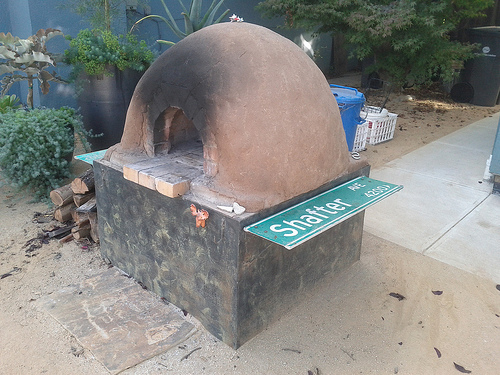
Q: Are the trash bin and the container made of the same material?
A: Yes, both the trash bin and the container are made of plastic.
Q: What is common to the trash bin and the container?
A: The material, both the trash bin and the container are plastic.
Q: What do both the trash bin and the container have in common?
A: The material, both the trash bin and the container are plastic.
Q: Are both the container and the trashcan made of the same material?
A: Yes, both the container and the trashcan are made of plastic.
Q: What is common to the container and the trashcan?
A: The material, both the container and the trashcan are plastic.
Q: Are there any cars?
A: No, there are no cars.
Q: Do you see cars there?
A: No, there are no cars.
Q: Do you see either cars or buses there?
A: No, there are no cars or buses.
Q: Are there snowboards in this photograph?
A: No, there are no snowboards.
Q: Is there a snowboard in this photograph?
A: No, there are no snowboards.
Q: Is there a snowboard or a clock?
A: No, there are no snowboards or clocks.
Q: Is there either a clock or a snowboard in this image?
A: No, there are no snowboards or clocks.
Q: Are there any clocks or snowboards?
A: No, there are no snowboards or clocks.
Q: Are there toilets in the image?
A: No, there are no toilets.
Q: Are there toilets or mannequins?
A: No, there are no toilets or mannequins.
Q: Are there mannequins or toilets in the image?
A: No, there are no toilets or mannequins.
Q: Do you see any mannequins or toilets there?
A: No, there are no toilets or mannequins.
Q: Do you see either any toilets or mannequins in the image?
A: No, there are no toilets or mannequins.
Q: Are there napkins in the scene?
A: No, there are no napkins.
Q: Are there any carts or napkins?
A: No, there are no napkins or carts.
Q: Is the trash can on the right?
A: Yes, the trash can is on the right of the image.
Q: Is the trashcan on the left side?
A: No, the trashcan is on the right of the image.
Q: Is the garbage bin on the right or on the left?
A: The garbage bin is on the right of the image.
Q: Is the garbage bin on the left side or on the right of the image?
A: The garbage bin is on the right of the image.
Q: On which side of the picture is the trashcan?
A: The trashcan is on the right of the image.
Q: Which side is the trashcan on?
A: The trashcan is on the right of the image.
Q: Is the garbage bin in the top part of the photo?
A: Yes, the garbage bin is in the top of the image.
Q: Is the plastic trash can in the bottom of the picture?
A: No, the trashcan is in the top of the image.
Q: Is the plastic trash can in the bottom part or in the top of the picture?
A: The trashcan is in the top of the image.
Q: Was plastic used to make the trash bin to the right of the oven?
A: Yes, the trashcan is made of plastic.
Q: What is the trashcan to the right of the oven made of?
A: The garbage can is made of plastic.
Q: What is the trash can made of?
A: The garbage can is made of plastic.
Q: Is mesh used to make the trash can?
A: No, the trash can is made of plastic.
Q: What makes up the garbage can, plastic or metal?
A: The garbage can is made of plastic.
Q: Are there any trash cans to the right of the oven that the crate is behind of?
A: Yes, there is a trash can to the right of the oven.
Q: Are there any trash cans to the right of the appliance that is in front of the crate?
A: Yes, there is a trash can to the right of the oven.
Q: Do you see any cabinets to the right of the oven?
A: No, there is a trash can to the right of the oven.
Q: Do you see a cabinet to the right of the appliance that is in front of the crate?
A: No, there is a trash can to the right of the oven.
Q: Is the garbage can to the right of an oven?
A: Yes, the garbage can is to the right of an oven.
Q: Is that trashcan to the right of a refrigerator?
A: No, the trashcan is to the right of an oven.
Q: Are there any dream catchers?
A: No, there are no dream catchers.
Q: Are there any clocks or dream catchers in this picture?
A: No, there are no dream catchers or clocks.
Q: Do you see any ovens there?
A: Yes, there is an oven.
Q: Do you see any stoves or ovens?
A: Yes, there is an oven.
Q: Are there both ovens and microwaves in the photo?
A: No, there is an oven but no microwaves.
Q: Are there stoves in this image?
A: No, there are no stoves.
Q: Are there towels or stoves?
A: No, there are no stoves or towels.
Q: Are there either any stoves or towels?
A: No, there are no stoves or towels.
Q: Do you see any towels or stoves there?
A: No, there are no stoves or towels.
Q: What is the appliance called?
A: The appliance is an oven.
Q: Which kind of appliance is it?
A: The appliance is an oven.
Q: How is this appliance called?
A: This is an oven.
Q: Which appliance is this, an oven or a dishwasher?
A: This is an oven.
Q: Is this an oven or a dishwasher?
A: This is an oven.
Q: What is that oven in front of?
A: The oven is in front of the crate.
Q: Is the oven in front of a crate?
A: Yes, the oven is in front of a crate.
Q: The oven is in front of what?
A: The oven is in front of the crate.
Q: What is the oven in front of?
A: The oven is in front of the crate.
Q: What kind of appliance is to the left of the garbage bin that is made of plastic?
A: The appliance is an oven.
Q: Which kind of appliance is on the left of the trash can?
A: The appliance is an oven.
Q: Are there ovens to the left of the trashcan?
A: Yes, there is an oven to the left of the trashcan.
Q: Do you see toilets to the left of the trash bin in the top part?
A: No, there is an oven to the left of the garbage can.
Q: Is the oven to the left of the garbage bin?
A: Yes, the oven is to the left of the garbage bin.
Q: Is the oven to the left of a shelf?
A: No, the oven is to the left of the garbage bin.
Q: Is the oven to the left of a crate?
A: Yes, the oven is to the left of a crate.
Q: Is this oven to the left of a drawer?
A: No, the oven is to the left of a crate.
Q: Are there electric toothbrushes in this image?
A: No, there are no electric toothbrushes.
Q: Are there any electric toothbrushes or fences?
A: No, there are no electric toothbrushes or fences.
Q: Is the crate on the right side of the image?
A: Yes, the crate is on the right of the image.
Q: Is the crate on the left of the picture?
A: No, the crate is on the right of the image.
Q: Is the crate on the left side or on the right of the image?
A: The crate is on the right of the image.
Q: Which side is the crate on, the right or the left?
A: The crate is on the right of the image.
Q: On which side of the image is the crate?
A: The crate is on the right of the image.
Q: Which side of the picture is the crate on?
A: The crate is on the right of the image.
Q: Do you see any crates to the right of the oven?
A: Yes, there is a crate to the right of the oven.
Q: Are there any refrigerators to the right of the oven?
A: No, there is a crate to the right of the oven.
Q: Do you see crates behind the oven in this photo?
A: Yes, there is a crate behind the oven.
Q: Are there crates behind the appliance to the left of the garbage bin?
A: Yes, there is a crate behind the oven.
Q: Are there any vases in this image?
A: No, there are no vases.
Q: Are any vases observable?
A: No, there are no vases.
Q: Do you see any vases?
A: No, there are no vases.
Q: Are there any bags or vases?
A: No, there are no vases or bags.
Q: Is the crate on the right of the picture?
A: Yes, the crate is on the right of the image.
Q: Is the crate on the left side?
A: No, the crate is on the right of the image.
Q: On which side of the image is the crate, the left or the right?
A: The crate is on the right of the image.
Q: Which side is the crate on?
A: The crate is on the right of the image.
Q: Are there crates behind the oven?
A: Yes, there is a crate behind the oven.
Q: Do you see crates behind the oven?
A: Yes, there is a crate behind the oven.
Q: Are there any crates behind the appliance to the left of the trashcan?
A: Yes, there is a crate behind the oven.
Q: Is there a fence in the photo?
A: No, there are no fences.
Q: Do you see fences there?
A: No, there are no fences.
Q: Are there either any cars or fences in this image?
A: No, there are no fences or cars.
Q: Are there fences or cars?
A: No, there are no fences or cars.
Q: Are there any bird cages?
A: No, there are no bird cages.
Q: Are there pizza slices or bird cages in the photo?
A: No, there are no bird cages or pizza slices.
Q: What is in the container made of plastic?
A: The plant is in the container.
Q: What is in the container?
A: The plant is in the container.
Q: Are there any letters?
A: Yes, there are letters.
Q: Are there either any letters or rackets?
A: Yes, there are letters.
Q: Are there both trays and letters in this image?
A: No, there are letters but no trays.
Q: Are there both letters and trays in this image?
A: No, there are letters but no trays.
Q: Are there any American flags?
A: No, there are no American flags.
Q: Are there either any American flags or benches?
A: No, there are no American flags or benches.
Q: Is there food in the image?
A: No, there is no food.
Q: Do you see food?
A: No, there is no food.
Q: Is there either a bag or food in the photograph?
A: No, there are no food or bags.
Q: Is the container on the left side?
A: Yes, the container is on the left of the image.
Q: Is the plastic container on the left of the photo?
A: Yes, the container is on the left of the image.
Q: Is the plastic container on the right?
A: No, the container is on the left of the image.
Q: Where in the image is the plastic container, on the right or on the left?
A: The container is on the left of the image.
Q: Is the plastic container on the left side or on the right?
A: The container is on the left of the image.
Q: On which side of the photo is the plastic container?
A: The container is on the left of the image.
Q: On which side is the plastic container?
A: The container is on the left of the image.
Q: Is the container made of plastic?
A: Yes, the container is made of plastic.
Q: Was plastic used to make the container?
A: Yes, the container is made of plastic.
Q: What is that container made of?
A: The container is made of plastic.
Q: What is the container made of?
A: The container is made of plastic.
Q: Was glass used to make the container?
A: No, the container is made of plastic.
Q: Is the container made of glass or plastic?
A: The container is made of plastic.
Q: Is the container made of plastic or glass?
A: The container is made of plastic.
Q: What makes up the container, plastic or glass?
A: The container is made of plastic.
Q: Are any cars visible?
A: No, there are no cars.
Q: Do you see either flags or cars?
A: No, there are no cars or flags.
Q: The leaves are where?
A: The leaves are on the ground.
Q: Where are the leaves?
A: The leaves are on the ground.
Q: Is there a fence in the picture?
A: No, there are no fences.